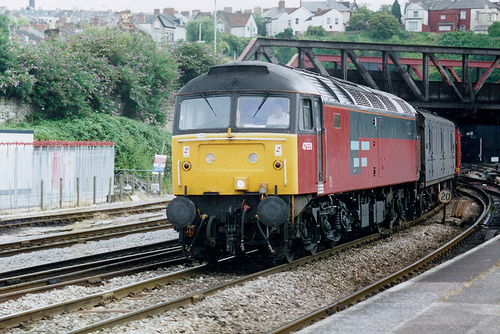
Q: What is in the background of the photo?
A: Houses.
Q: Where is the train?
A: On the track.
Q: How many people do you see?
A: 1.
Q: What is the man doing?
A: Driving the train.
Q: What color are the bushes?
A: Green.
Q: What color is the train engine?
A: Red, yellow, and black.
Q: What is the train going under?
A: A bridge.